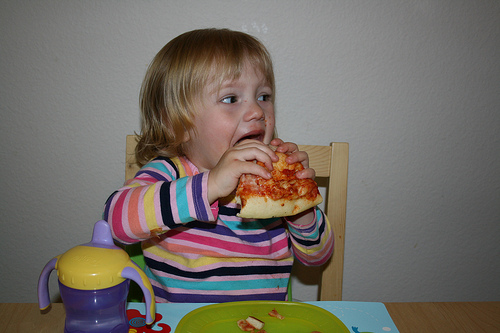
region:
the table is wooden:
[205, 191, 461, 331]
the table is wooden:
[297, 244, 421, 331]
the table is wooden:
[328, 202, 473, 331]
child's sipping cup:
[36, 222, 158, 332]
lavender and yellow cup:
[37, 218, 156, 330]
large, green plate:
[174, 302, 351, 330]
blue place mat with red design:
[124, 302, 402, 330]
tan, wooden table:
[1, 301, 498, 329]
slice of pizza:
[237, 146, 322, 218]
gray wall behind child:
[0, 0, 497, 300]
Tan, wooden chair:
[128, 137, 349, 299]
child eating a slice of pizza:
[102, 30, 334, 300]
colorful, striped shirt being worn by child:
[104, 153, 335, 300]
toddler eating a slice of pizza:
[98, 6, 369, 321]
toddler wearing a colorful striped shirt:
[100, 13, 341, 311]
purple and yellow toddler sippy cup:
[36, 211, 166, 331]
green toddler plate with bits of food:
[163, 284, 338, 331]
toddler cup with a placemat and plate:
[38, 226, 393, 332]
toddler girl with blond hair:
[120, 6, 297, 186]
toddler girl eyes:
[212, 76, 294, 113]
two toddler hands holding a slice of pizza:
[211, 126, 354, 213]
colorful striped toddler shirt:
[111, 153, 253, 292]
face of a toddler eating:
[138, 3, 290, 160]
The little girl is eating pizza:
[104, 31, 288, 326]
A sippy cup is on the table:
[33, 222, 139, 330]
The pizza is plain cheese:
[239, 151, 339, 233]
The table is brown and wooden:
[411, 301, 428, 331]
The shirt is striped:
[130, 142, 301, 330]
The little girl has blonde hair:
[139, 10, 286, 162]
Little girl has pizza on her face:
[221, 90, 293, 145]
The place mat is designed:
[121, 302, 461, 331]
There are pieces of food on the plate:
[227, 294, 286, 331]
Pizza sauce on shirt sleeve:
[140, 220, 173, 247]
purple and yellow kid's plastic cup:
[35, 230, 146, 332]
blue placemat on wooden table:
[129, 297, 387, 325]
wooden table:
[0, 302, 492, 327]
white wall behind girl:
[1, 0, 498, 298]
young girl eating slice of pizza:
[117, 30, 318, 290]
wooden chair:
[130, 150, 345, 298]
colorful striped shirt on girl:
[129, 163, 320, 285]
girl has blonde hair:
[134, 32, 270, 152]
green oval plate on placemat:
[180, 302, 346, 331]